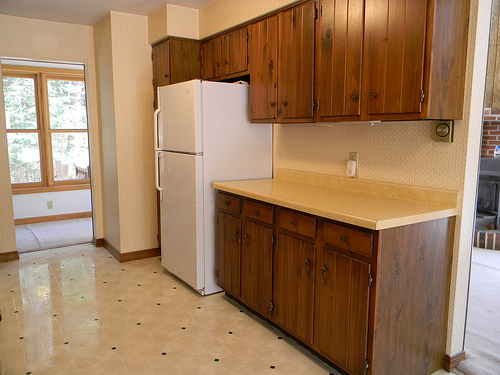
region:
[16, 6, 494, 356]
Photo was taken indoors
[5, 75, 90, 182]
Windows are in the background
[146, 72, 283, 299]
A refrigerator is in the foreground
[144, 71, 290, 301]
Refrigerator is white in color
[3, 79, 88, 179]
Trees are outside the window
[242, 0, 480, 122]
Kitchen cabinets are in view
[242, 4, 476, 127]
Kitchen cabinets are made out of wood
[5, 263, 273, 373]
The floor has black diamond shaped patterns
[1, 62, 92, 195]
A white frame is around the window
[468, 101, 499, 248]
View of a Brick wall is in the background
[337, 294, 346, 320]
the drawer is wooden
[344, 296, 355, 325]
the drawer is wooden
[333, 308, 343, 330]
the drawer is wooden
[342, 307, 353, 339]
the drawer is wooden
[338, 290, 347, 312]
the drawer is wooden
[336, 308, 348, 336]
the drawer is wooden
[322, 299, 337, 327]
the drawer is wooden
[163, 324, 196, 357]
part of a floor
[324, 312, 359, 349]
part of a board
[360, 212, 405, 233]
edge fo a surface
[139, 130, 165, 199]
part of a handle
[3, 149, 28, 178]
part of a window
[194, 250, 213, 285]
edge of a fridge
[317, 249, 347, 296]
part of a handle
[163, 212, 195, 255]
part of a fridge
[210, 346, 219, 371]
black mark is spotted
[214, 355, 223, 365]
black mark is spotted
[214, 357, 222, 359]
black mark is spotted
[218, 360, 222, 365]
black mark is spotted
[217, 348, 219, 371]
black mark is spotted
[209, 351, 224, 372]
black mark is spotted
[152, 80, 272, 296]
A white colored refrigerator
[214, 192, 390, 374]
Wooden cabinetries with metal handles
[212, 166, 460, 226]
Counterop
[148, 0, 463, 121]
Wooden cabinetries with metal handles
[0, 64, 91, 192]
A large window with wood trimmings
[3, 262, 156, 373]
Linoleum kitchen flooring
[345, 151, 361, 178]
A power outlet with air freshener plugged in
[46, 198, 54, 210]
A wall power outlet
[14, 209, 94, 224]
Wooden baseboard trimming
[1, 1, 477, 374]
A kitchen